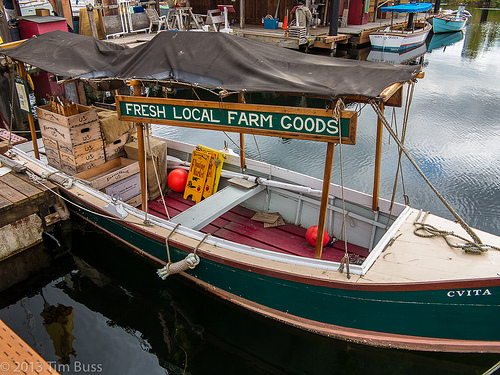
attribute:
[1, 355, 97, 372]
owner — here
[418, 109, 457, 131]
water — small, reflected, green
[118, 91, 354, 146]
advertisement — yellow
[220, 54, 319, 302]
boat — green, white, teal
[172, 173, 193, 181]
bumper — orange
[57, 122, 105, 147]
crates — wooden, brown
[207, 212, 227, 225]
bench — wooden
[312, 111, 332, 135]
sign — yellow, green, wooden, white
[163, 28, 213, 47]
tent — black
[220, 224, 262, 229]
floor — red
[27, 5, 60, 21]
chairs — white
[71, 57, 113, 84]
canopy — blue